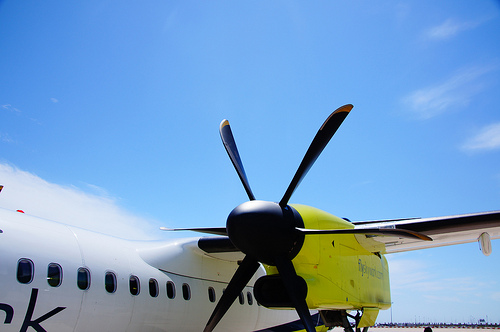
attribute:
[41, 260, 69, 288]
window — small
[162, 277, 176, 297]
window —  small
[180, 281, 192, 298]
window —  small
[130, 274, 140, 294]
window —  small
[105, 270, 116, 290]
window —  small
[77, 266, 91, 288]
window —  small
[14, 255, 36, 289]
window — small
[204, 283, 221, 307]
window — small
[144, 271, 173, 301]
window — Small 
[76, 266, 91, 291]
window — small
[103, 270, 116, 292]
window — small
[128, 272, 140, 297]
window — small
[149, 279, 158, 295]
window — small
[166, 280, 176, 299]
window —  small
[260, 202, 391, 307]
part — yellow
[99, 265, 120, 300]
window — small